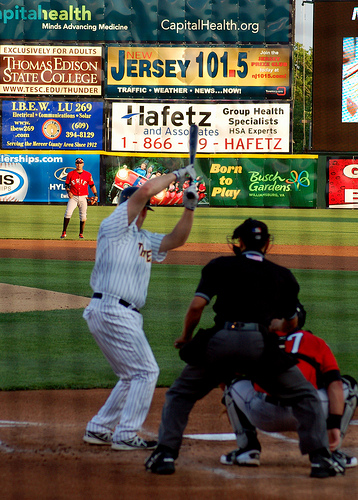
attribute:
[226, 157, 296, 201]
sign — busch garden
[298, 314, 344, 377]
catcher — down, ready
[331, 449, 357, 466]
shoes — black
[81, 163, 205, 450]
batter — ready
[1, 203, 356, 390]
grass — green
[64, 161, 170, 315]
shirt — black